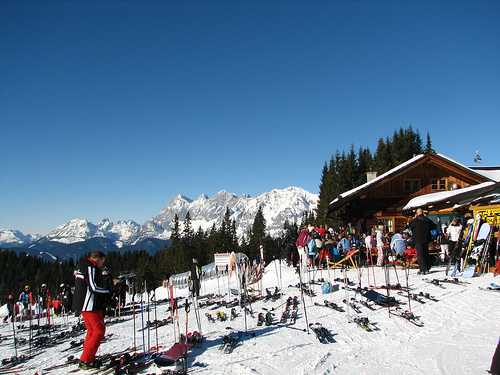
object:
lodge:
[323, 148, 499, 267]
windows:
[402, 178, 421, 192]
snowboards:
[460, 222, 491, 279]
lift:
[473, 148, 483, 163]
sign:
[214, 253, 233, 271]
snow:
[0, 258, 499, 374]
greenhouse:
[169, 252, 251, 290]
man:
[69, 250, 119, 372]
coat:
[71, 258, 112, 313]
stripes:
[92, 267, 105, 289]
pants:
[79, 310, 107, 364]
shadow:
[99, 322, 295, 372]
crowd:
[281, 209, 415, 275]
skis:
[309, 323, 327, 345]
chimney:
[365, 165, 377, 183]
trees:
[314, 160, 336, 228]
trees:
[247, 204, 268, 266]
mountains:
[21, 218, 110, 249]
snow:
[0, 186, 322, 248]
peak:
[173, 193, 191, 205]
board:
[153, 340, 194, 368]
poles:
[183, 299, 189, 375]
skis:
[395, 306, 424, 324]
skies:
[0, 1, 500, 237]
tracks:
[335, 324, 355, 343]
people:
[188, 257, 203, 299]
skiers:
[19, 285, 32, 317]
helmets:
[41, 284, 48, 291]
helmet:
[25, 285, 30, 289]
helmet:
[59, 283, 66, 289]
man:
[408, 208, 438, 275]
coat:
[408, 214, 437, 245]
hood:
[414, 215, 431, 225]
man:
[443, 216, 467, 266]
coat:
[445, 221, 462, 242]